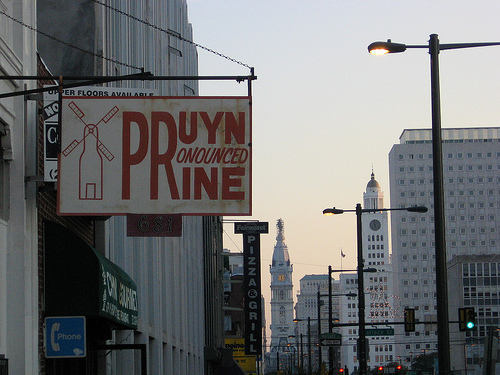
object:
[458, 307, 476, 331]
signal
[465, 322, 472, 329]
light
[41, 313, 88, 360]
sign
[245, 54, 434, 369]
city street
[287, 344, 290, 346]
light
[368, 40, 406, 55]
light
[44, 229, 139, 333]
canopy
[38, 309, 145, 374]
doorway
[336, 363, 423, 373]
streelights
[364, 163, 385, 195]
windmill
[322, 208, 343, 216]
light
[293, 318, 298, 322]
overhead streetlight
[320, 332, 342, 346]
sign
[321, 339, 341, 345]
arrow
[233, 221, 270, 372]
black sign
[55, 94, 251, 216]
sign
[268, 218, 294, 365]
skyscraper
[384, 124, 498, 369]
skyscraper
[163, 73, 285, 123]
wall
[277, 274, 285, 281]
window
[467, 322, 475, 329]
light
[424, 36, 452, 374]
lamp post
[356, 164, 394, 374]
clocktower